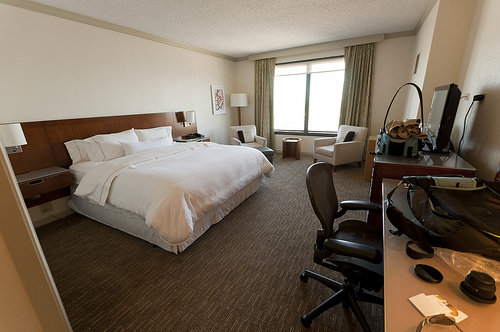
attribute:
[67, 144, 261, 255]
bed — king sized, white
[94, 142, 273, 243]
comforter — white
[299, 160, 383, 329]
chair — swivel, black, empty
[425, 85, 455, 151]
tv — flat screen, black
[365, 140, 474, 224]
dresser — wood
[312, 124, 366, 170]
chair — white, empty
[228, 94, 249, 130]
lamp — white, off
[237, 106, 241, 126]
pole — wood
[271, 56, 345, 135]
window — large, open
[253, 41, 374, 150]
drapes — open, green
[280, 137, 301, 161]
table — small, cylindrical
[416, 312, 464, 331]
glasses — brown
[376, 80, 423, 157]
bag — blue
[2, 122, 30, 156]
lamp — white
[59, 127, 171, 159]
pillows — white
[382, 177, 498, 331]
desk — long, brown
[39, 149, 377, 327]
carpet — brown, tan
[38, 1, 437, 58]
ceiling — white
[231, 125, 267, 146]
chair — white